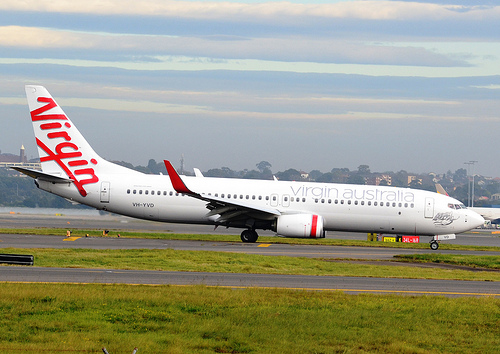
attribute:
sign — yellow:
[382, 235, 399, 244]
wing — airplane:
[132, 154, 215, 203]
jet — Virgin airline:
[33, 82, 498, 249]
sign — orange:
[401, 232, 423, 244]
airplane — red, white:
[11, 80, 489, 248]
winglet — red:
[163, 160, 189, 194]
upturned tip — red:
[160, 159, 188, 194]